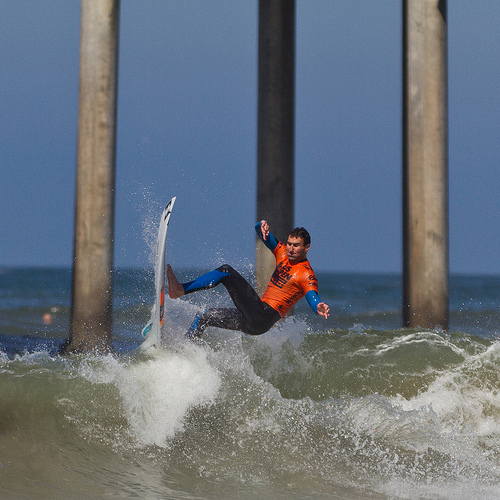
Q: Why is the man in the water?
A: Surfing.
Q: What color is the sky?
A: Blue.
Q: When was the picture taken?
A: Daytime.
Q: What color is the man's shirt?
A: Orange.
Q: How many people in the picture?
A: One.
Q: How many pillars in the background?
A: Three.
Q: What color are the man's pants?
A: Black.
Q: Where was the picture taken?
A: At a beach.